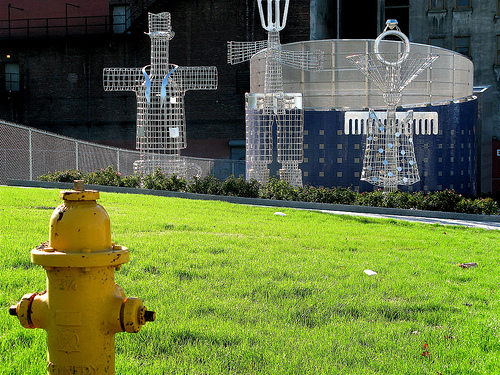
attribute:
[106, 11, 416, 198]
statues — metal, wire, airy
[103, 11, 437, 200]
figures — grids, human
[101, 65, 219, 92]
arms — out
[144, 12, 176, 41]
hat — on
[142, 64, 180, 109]
tie — undone, wrapped, open, blue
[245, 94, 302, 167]
trousers — cylindrical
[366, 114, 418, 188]
dots — blue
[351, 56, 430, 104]
arms — reaching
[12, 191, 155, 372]
hydrant — yellow, bright, metal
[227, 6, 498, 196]
wall — blue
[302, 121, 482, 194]
squares — gray, white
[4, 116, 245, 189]
fence — chain, gray, metal, curved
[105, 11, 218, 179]
sculpture — metal, medium, wire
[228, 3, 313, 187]
structure — tall, metal, wire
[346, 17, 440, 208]
sculpture — wire, metal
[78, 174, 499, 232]
path — concrete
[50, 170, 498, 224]
bushes — green, short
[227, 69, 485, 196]
metal — curved, shiny, blue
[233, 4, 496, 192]
building — white, blue, curved, gray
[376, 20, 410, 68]
ring — large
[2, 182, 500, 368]
grass — green, grassy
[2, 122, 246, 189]
chain — silver, grey, metal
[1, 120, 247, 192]
fence — silver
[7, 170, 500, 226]
curb — cement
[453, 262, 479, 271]
rock — laying, small, grey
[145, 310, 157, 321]
bolt — brown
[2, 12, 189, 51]
railing — metal, black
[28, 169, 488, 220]
blooms — purple